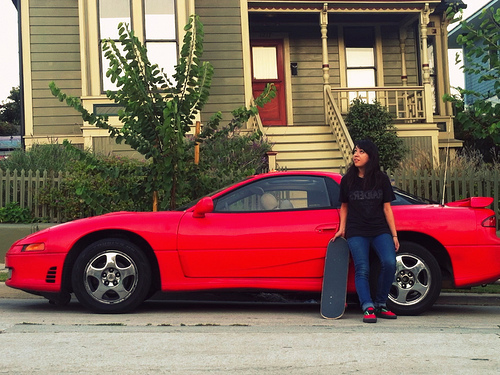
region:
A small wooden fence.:
[1, 167, 498, 223]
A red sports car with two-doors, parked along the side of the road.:
[6, 165, 498, 315]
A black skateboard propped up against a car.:
[319, 234, 349, 322]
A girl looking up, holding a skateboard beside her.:
[320, 139, 400, 329]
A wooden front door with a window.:
[250, 37, 287, 124]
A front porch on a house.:
[258, 90, 426, 125]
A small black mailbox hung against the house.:
[289, 61, 299, 76]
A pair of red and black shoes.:
[363, 307, 397, 321]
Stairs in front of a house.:
[263, 124, 348, 174]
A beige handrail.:
[324, 87, 365, 154]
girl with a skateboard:
[314, 139, 401, 325]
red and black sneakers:
[355, 303, 402, 329]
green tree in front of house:
[72, 31, 254, 169]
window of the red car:
[207, 172, 334, 214]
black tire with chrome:
[76, 233, 153, 308]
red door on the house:
[245, 38, 290, 131]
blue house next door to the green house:
[447, 17, 497, 112]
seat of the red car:
[258, 190, 296, 217]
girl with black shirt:
[332, 134, 407, 330]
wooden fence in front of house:
[6, 167, 53, 220]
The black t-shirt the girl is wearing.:
[339, 161, 398, 228]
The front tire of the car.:
[72, 243, 159, 307]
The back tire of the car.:
[379, 225, 437, 315]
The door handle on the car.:
[312, 224, 339, 234]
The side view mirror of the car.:
[197, 188, 217, 220]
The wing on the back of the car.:
[453, 182, 492, 211]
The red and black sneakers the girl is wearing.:
[357, 307, 397, 319]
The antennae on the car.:
[436, 132, 455, 214]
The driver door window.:
[222, 173, 329, 209]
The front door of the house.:
[248, 45, 288, 124]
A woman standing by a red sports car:
[328, 123, 413, 328]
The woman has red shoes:
[352, 294, 407, 326]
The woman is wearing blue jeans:
[345, 222, 409, 313]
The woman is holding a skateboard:
[312, 218, 357, 327]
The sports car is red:
[7, 148, 494, 328]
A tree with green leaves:
[31, 27, 247, 227]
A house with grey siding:
[4, 2, 465, 135]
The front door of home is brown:
[223, 22, 313, 133]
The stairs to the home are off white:
[243, 112, 378, 229]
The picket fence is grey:
[1, 153, 201, 228]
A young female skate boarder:
[321, 145, 401, 321]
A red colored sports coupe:
[2, 174, 498, 309]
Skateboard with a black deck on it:
[319, 229, 350, 319]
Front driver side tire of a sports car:
[65, 231, 152, 311]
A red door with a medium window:
[243, 34, 286, 124]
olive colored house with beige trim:
[10, 2, 460, 175]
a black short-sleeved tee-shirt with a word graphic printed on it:
[339, 163, 388, 232]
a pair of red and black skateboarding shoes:
[358, 307, 398, 324]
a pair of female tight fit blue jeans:
[348, 231, 397, 310]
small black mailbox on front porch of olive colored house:
[289, 58, 300, 79]